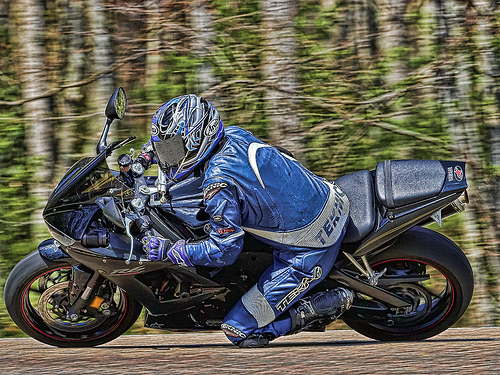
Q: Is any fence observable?
A: No, there are no fences.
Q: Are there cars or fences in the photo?
A: No, there are no fences or cars.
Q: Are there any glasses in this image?
A: No, there are no glasses.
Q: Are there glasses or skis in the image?
A: No, there are no glasses or skis.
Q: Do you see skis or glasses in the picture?
A: No, there are no glasses or skis.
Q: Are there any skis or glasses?
A: No, there are no glasses or skis.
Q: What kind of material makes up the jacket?
A: The jacket is made of leather.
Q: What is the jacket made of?
A: The jacket is made of leather.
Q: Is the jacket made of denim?
A: No, the jacket is made of leather.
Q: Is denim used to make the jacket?
A: No, the jacket is made of leather.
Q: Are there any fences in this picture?
A: No, there are no fences.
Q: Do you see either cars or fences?
A: No, there are no fences or cars.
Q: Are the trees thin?
A: Yes, the trees are thin.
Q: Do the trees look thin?
A: Yes, the trees are thin.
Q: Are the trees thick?
A: No, the trees are thin.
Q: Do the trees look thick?
A: No, the trees are thin.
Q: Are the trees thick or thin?
A: The trees are thin.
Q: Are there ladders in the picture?
A: No, there are no ladders.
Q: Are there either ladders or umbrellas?
A: No, there are no ladders or umbrellas.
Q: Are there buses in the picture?
A: No, there are no buses.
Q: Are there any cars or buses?
A: No, there are no buses or cars.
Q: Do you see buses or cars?
A: No, there are no buses or cars.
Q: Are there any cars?
A: No, there are no cars.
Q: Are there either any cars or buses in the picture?
A: No, there are no cars or buses.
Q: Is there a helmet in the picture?
A: Yes, there is a helmet.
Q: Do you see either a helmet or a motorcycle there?
A: Yes, there is a helmet.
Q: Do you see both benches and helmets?
A: No, there is a helmet but no benches.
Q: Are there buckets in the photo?
A: No, there are no buckets.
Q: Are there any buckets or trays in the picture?
A: No, there are no buckets or trays.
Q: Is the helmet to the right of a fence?
A: No, the helmet is to the right of the mirror.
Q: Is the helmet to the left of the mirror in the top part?
A: No, the helmet is to the right of the mirror.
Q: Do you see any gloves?
A: Yes, there are gloves.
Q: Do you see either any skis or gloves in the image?
A: Yes, there are gloves.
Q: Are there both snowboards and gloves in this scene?
A: No, there are gloves but no snowboards.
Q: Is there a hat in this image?
A: No, there are no hats.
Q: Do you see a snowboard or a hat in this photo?
A: No, there are no hats or snowboards.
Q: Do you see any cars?
A: No, there are no cars.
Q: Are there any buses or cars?
A: No, there are no cars or buses.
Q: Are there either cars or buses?
A: No, there are no cars or buses.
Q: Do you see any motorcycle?
A: Yes, there is a motorcycle.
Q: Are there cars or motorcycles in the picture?
A: Yes, there is a motorcycle.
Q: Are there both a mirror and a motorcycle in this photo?
A: Yes, there are both a motorcycle and a mirror.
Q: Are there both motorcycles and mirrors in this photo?
A: Yes, there are both a motorcycle and a mirror.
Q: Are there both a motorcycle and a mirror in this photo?
A: Yes, there are both a motorcycle and a mirror.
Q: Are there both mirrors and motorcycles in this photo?
A: Yes, there are both a motorcycle and a mirror.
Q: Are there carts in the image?
A: No, there are no carts.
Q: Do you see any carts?
A: No, there are no carts.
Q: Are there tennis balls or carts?
A: No, there are no carts or tennis balls.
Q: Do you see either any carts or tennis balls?
A: No, there are no carts or tennis balls.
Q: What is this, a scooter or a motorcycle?
A: This is a motorcycle.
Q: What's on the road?
A: The motorbike is on the road.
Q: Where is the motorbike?
A: The motorbike is on the road.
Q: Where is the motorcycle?
A: The motorbike is on the road.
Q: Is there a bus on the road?
A: No, there is a motorcycle on the road.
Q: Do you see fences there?
A: No, there are no fences.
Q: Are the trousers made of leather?
A: Yes, the trousers are made of leather.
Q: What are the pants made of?
A: The pants are made of leather.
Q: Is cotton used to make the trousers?
A: No, the trousers are made of leather.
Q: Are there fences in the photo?
A: No, there are no fences.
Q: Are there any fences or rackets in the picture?
A: No, there are no fences or rackets.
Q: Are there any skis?
A: No, there are no skis.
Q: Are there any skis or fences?
A: No, there are no skis or fences.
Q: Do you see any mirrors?
A: Yes, there is a mirror.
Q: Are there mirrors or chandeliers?
A: Yes, there is a mirror.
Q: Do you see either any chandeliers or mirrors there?
A: Yes, there is a mirror.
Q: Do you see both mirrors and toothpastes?
A: No, there is a mirror but no toothpastes.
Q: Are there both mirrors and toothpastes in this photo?
A: No, there is a mirror but no toothpastes.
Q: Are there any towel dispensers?
A: No, there are no towel dispensers.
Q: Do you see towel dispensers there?
A: No, there are no towel dispensers.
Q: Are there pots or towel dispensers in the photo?
A: No, there are no towel dispensers or pots.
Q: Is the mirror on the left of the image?
A: Yes, the mirror is on the left of the image.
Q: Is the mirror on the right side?
A: No, the mirror is on the left of the image.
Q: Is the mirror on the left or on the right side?
A: The mirror is on the left of the image.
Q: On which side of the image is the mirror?
A: The mirror is on the left of the image.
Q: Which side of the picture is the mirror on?
A: The mirror is on the left of the image.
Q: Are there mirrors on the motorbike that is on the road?
A: Yes, there is a mirror on the motorcycle.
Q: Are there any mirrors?
A: Yes, there is a mirror.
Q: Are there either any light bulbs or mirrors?
A: Yes, there is a mirror.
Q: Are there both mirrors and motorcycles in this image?
A: Yes, there are both a mirror and a motorcycle.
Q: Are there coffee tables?
A: No, there are no coffee tables.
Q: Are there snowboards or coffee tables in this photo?
A: No, there are no coffee tables or snowboards.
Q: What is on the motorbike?
A: The mirror is on the motorbike.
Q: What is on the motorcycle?
A: The mirror is on the motorbike.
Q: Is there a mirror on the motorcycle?
A: Yes, there is a mirror on the motorcycle.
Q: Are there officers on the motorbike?
A: No, there is a mirror on the motorbike.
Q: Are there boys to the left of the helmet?
A: No, there is a mirror to the left of the helmet.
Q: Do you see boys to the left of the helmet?
A: No, there is a mirror to the left of the helmet.